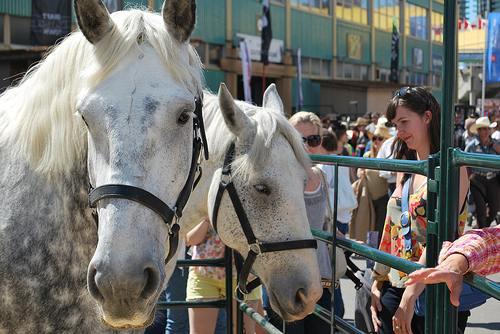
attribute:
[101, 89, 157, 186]
dots — black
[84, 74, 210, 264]
bridle strap — black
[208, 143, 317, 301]
bridle strap — black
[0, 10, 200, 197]
hair — white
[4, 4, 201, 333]
horse — standing, foreground, grey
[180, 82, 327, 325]
horse — standing, foreground, grey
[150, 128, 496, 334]
railing — green, metal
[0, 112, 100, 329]
pattern — grey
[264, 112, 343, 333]
woman — blonde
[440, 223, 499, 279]
sleeve — designed, pink, orange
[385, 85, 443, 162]
hair — brown, long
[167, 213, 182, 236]
ring — silver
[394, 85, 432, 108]
sunglasses — black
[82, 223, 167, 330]
nose — grey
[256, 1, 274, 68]
flag — black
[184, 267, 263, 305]
shorts — yellow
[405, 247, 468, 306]
hand — outreached, reaching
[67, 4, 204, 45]
ears — white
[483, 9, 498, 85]
flag — blue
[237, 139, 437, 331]
gate — green